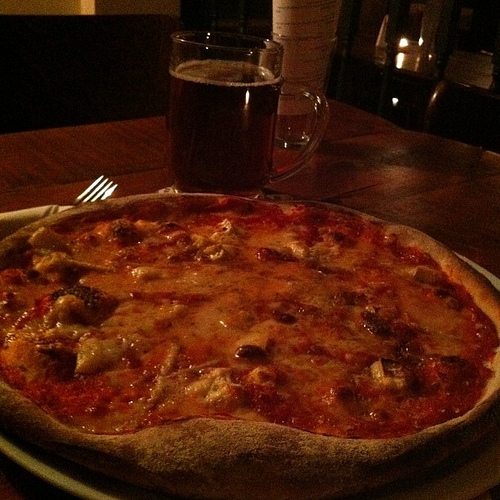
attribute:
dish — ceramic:
[1, 188, 498, 499]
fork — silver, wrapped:
[0, 169, 128, 253]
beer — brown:
[165, 56, 285, 204]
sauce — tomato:
[4, 203, 496, 435]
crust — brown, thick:
[0, 188, 499, 491]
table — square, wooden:
[0, 93, 498, 499]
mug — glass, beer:
[170, 36, 347, 205]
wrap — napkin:
[0, 201, 82, 228]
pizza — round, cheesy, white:
[1, 175, 498, 500]